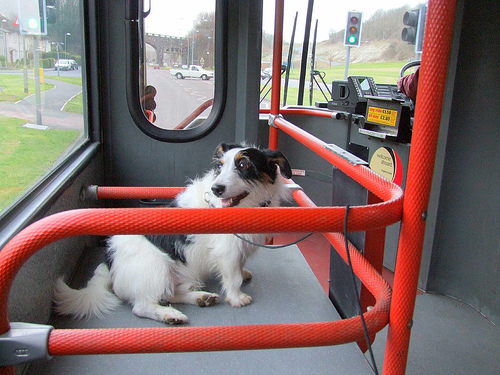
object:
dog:
[51, 137, 303, 321]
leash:
[203, 196, 379, 374]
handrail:
[3, 114, 404, 359]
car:
[53, 57, 71, 70]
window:
[0, 0, 97, 219]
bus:
[0, 0, 496, 370]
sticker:
[365, 105, 400, 127]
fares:
[379, 108, 391, 121]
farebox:
[359, 92, 408, 140]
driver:
[396, 59, 420, 105]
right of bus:
[288, 0, 493, 316]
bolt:
[421, 209, 428, 220]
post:
[387, 0, 466, 372]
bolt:
[407, 319, 414, 329]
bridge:
[145, 32, 198, 66]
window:
[136, 1, 226, 139]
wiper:
[283, 9, 300, 107]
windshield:
[262, 1, 426, 116]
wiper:
[307, 17, 321, 107]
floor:
[269, 210, 426, 323]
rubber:
[123, 3, 233, 142]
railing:
[173, 100, 216, 132]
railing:
[258, 104, 332, 120]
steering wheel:
[399, 60, 420, 88]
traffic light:
[342, 8, 364, 78]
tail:
[49, 256, 126, 320]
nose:
[210, 183, 226, 197]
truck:
[169, 65, 214, 81]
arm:
[398, 66, 418, 98]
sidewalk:
[11, 66, 90, 132]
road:
[141, 59, 210, 107]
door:
[100, 2, 262, 207]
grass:
[2, 67, 72, 172]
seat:
[33, 183, 378, 374]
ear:
[262, 147, 292, 179]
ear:
[211, 140, 242, 160]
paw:
[227, 290, 252, 306]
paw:
[164, 311, 188, 326]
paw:
[240, 269, 253, 280]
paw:
[195, 291, 220, 306]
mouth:
[220, 191, 250, 206]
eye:
[238, 161, 247, 169]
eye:
[217, 162, 223, 168]